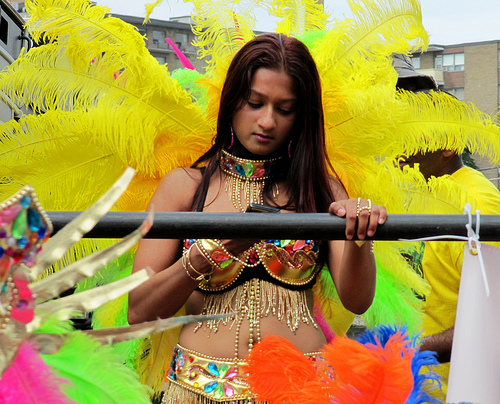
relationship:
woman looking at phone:
[125, 32, 382, 404] [244, 201, 279, 213]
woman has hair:
[125, 32, 382, 404] [187, 32, 350, 210]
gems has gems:
[219, 149, 290, 183] [220, 154, 265, 181]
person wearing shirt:
[402, 85, 499, 402] [397, 159, 499, 402]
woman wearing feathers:
[95, 32, 394, 402] [33, 11, 463, 168]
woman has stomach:
[125, 32, 382, 404] [179, 293, 327, 361]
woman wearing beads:
[125, 32, 382, 404] [188, 276, 330, 343]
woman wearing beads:
[125, 32, 382, 404] [214, 166, 301, 211]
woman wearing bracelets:
[125, 32, 382, 404] [179, 240, 234, 284]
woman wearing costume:
[125, 32, 382, 404] [160, 147, 325, 403]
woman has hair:
[125, 32, 382, 404] [187, 32, 349, 216]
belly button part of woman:
[242, 332, 264, 352] [125, 32, 382, 404]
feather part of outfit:
[327, 87, 498, 169] [7, 0, 497, 400]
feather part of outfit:
[0, 0, 499, 404] [7, 0, 497, 400]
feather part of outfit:
[0, 0, 499, 404] [118, 22, 388, 403]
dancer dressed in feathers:
[126, 29, 386, 401] [325, 37, 489, 205]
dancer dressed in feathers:
[126, 29, 386, 401] [349, 60, 499, 160]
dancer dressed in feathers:
[126, 29, 386, 401] [24, 13, 479, 207]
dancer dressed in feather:
[126, 29, 386, 401] [0, 0, 499, 404]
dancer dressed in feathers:
[126, 29, 386, 401] [321, 1, 433, 88]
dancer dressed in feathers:
[126, 29, 386, 401] [326, 90, 499, 161]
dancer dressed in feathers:
[126, 29, 386, 401] [330, 151, 477, 216]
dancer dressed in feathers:
[126, 29, 386, 401] [1, 3, 211, 143]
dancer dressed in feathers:
[126, 29, 386, 401] [3, 115, 128, 175]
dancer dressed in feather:
[104, 28, 441, 402] [1, 38, 214, 135]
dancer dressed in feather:
[104, 28, 441, 402] [185, 0, 253, 67]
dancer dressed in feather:
[104, 28, 441, 402] [327, 87, 498, 169]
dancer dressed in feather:
[104, 28, 441, 402] [309, 0, 431, 91]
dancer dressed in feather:
[104, 28, 441, 402] [1, 134, 130, 207]